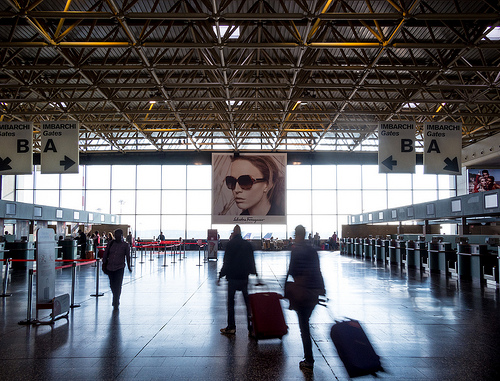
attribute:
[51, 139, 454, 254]
windows — large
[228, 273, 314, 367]
suitcase — large, red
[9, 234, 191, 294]
rope — red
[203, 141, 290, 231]
picture — large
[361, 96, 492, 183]
sign — white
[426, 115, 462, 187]
sign — white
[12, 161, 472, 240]
windows — airport